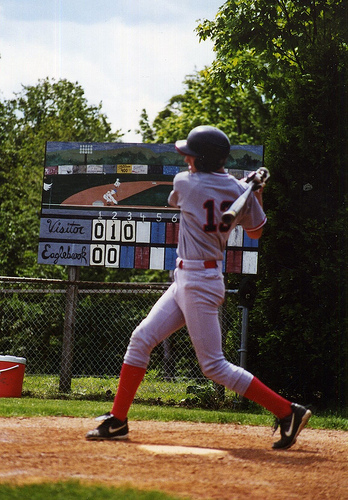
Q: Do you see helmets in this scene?
A: Yes, there is a helmet.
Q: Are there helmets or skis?
A: Yes, there is a helmet.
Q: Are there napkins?
A: No, there are no napkins.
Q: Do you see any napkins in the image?
A: No, there are no napkins.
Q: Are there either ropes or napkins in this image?
A: No, there are no napkins or ropes.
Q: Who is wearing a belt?
A: The man is wearing a belt.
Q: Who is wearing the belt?
A: The man is wearing a belt.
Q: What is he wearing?
A: The man is wearing a belt.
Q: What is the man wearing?
A: The man is wearing a belt.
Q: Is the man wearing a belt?
A: Yes, the man is wearing a belt.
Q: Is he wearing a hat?
A: No, the man is wearing a belt.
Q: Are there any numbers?
A: Yes, there are numbers.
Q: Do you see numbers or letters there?
A: Yes, there are numbers.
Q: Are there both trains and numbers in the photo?
A: No, there are numbers but no trains.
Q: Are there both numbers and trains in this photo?
A: No, there are numbers but no trains.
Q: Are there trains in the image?
A: No, there are no trains.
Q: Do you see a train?
A: No, there are no trains.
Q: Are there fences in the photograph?
A: Yes, there is a fence.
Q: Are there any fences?
A: Yes, there is a fence.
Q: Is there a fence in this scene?
A: Yes, there is a fence.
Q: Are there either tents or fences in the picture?
A: Yes, there is a fence.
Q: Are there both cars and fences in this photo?
A: No, there is a fence but no cars.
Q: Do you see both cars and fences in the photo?
A: No, there is a fence but no cars.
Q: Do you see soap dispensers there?
A: No, there are no soap dispensers.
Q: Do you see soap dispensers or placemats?
A: No, there are no soap dispensers or placemats.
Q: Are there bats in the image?
A: Yes, there is a bat.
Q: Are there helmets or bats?
A: Yes, there is a bat.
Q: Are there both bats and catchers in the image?
A: No, there is a bat but no catchers.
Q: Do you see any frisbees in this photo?
A: No, there are no frisbees.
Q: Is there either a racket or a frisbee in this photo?
A: No, there are no frisbees or rackets.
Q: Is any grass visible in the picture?
A: Yes, there is grass.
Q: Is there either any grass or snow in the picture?
A: Yes, there is grass.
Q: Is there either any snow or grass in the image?
A: Yes, there is grass.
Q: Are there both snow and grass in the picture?
A: No, there is grass but no snow.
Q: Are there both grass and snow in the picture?
A: No, there is grass but no snow.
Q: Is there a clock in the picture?
A: No, there are no clocks.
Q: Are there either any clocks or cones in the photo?
A: No, there are no clocks or cones.